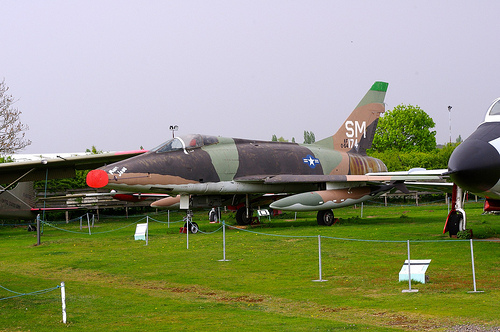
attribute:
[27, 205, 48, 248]
pole — short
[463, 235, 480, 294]
pole — small, white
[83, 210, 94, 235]
pole — short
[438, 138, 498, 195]
nose — black, color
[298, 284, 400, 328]
grass field — green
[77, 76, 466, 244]
plane — big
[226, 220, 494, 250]
line — green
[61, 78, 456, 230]
aircraft — body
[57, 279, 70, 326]
pole — short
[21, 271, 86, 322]
grass — a patch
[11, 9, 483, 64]
sky — smoggy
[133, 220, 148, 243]
sign — white, blue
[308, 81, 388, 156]
tail — wing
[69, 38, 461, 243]
plane — big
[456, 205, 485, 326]
pole — short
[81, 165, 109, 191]
nose — red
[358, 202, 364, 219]
pole — short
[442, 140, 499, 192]
nose — black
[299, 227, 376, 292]
grass — a patch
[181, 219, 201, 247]
pole — short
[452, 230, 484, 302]
pole — short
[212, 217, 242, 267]
pole — short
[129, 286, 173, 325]
grass — a patch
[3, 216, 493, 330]
grass — dead, a strip of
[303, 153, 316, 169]
circle — blue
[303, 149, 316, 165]
star — white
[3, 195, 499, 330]
field — green , grass